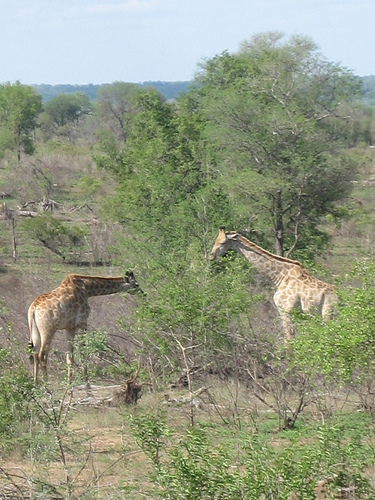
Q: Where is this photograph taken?
A: In the African safari.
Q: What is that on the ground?
A: A log.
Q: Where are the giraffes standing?
A: In a field of bushes and trees.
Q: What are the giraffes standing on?
A: The brown ground and shrubs.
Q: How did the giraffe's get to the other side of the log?
A: They stepped over it.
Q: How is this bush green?
A: From water.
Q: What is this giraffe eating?
A: Leaves from a tree.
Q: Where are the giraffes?
A: In an open park.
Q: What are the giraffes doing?
A: Eating leaves from the branches.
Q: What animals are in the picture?
A: Giraffes.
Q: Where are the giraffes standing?
A: Among trees.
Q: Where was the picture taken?
A: The bush.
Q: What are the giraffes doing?
A: Eating.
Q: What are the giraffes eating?
A: Tree leaves.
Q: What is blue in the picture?
A: The sky.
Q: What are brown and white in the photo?
A: Giraffes.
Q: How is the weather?
A: Sunny.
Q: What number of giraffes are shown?
A: Two.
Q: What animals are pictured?
A: Giraffes.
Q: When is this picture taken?
A: Daytime.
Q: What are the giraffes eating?
A: A tree.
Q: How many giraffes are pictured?
A: Two.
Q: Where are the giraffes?
A: A field.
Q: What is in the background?
A: Trees.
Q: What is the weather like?
A: Sunny.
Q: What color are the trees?
A: Green.